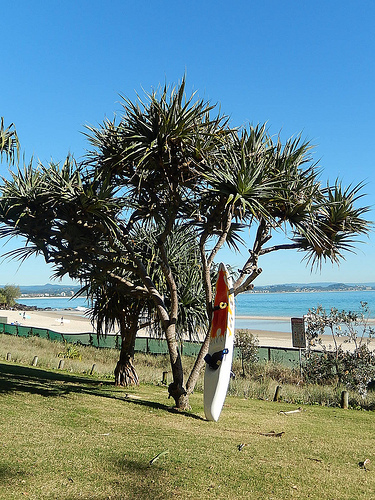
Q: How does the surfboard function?
A: Floats.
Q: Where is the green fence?
A: Behind the trees.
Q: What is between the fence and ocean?
A: Sand.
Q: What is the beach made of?
A: Sand.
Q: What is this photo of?
A: A park.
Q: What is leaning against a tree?
A: A surfboard.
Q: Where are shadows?
A: On the grass.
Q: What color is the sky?
A: Blue.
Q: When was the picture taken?
A: During a sunny day.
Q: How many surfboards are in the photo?
A: One.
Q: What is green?
A: The grass.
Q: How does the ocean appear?
A: Calm.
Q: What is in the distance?
A: Mountains.